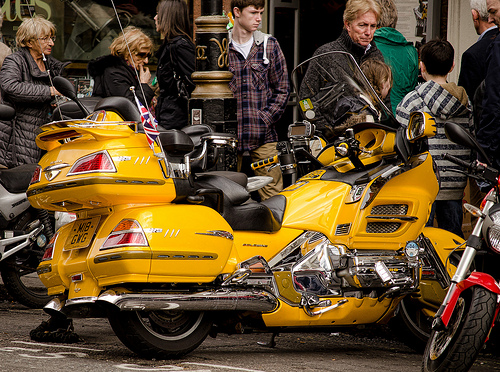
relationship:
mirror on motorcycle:
[408, 109, 433, 144] [27, 106, 476, 356]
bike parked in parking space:
[26, 50, 475, 358] [2, 306, 483, 366]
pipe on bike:
[43, 279, 281, 319] [23, 49, 480, 349]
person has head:
[0, 15, 70, 170] [346, 54, 396, 101]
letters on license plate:
[68, 217, 93, 244] [61, 214, 104, 252]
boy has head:
[225, 0, 290, 200] [469, 2, 484, 40]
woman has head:
[152, 0, 201, 129] [145, 1, 195, 42]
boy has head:
[225, 0, 290, 200] [109, 28, 159, 71]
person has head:
[0, 15, 70, 170] [9, 10, 66, 59]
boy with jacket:
[225, 0, 290, 200] [218, 39, 287, 131]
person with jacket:
[0, 15, 70, 170] [4, 46, 41, 172]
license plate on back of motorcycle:
[61, 219, 107, 251] [69, 130, 431, 310]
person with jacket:
[0, 15, 70, 170] [380, 36, 418, 92]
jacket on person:
[380, 36, 418, 92] [0, 15, 70, 170]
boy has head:
[225, 0, 290, 200] [377, 2, 395, 34]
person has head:
[377, 8, 408, 68] [376, 8, 395, 32]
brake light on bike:
[70, 151, 116, 179] [21, 82, 471, 352]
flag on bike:
[132, 96, 168, 153] [33, 93, 451, 330]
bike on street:
[21, 82, 471, 352] [5, 150, 485, 365]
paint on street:
[11, 340, 246, 369] [1, 233, 486, 366]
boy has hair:
[404, 39, 470, 212] [414, 39, 449, 73]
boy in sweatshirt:
[225, 0, 290, 200] [224, 30, 275, 137]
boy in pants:
[225, 0, 290, 200] [242, 134, 296, 194]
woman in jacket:
[152, 2, 203, 133] [149, 34, 198, 129]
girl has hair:
[326, 59, 411, 139] [355, 54, 390, 97]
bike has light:
[26, 50, 475, 358] [72, 143, 120, 173]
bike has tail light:
[26, 50, 475, 358] [99, 230, 150, 251]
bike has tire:
[26, 50, 475, 358] [102, 301, 222, 361]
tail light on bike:
[103, 220, 150, 254] [26, 50, 475, 358]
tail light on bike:
[99, 230, 150, 251] [26, 50, 475, 358]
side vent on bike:
[364, 198, 421, 236] [26, 50, 475, 358]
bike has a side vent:
[26, 50, 475, 358] [364, 198, 421, 236]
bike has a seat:
[26, 50, 475, 358] [204, 168, 277, 230]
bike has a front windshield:
[26, 50, 475, 358] [306, 52, 378, 130]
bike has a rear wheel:
[26, 50, 475, 358] [115, 313, 213, 361]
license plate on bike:
[61, 214, 104, 252] [33, 93, 451, 330]